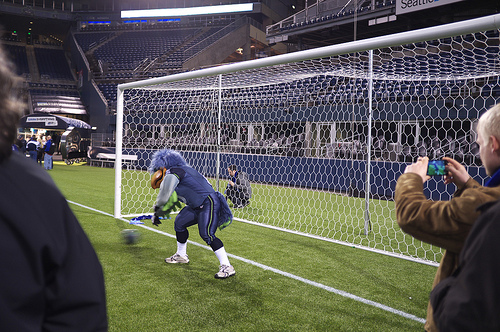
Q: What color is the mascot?
A: He is blue.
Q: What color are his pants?
A: Blue.